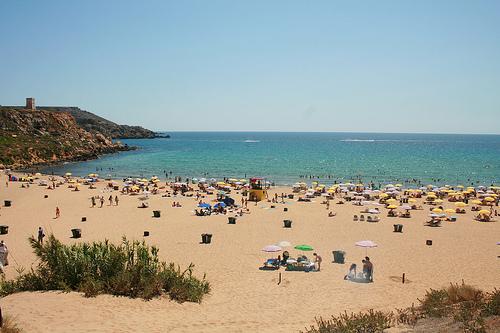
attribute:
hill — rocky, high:
[1, 107, 128, 169]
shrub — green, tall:
[2, 234, 211, 304]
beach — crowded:
[0, 173, 499, 332]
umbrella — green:
[294, 243, 313, 251]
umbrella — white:
[260, 243, 283, 252]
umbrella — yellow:
[477, 209, 491, 215]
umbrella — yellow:
[386, 203, 395, 210]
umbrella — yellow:
[444, 208, 454, 214]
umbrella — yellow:
[432, 199, 442, 203]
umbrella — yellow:
[407, 198, 417, 204]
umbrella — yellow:
[453, 201, 465, 208]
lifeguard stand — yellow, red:
[247, 177, 269, 200]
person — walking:
[115, 195, 119, 206]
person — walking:
[108, 194, 114, 205]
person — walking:
[99, 196, 106, 207]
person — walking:
[91, 196, 97, 209]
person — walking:
[54, 206, 61, 219]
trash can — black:
[70, 227, 83, 238]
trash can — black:
[152, 210, 160, 217]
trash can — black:
[200, 233, 213, 243]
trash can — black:
[283, 219, 292, 229]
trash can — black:
[392, 223, 403, 233]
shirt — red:
[56, 209, 61, 214]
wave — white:
[241, 138, 262, 144]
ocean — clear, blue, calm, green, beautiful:
[18, 131, 499, 188]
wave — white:
[335, 138, 376, 140]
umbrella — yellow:
[399, 205, 411, 211]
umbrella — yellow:
[482, 196, 495, 204]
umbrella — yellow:
[469, 200, 482, 205]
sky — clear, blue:
[2, 1, 500, 136]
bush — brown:
[398, 278, 499, 332]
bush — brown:
[302, 310, 396, 332]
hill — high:
[38, 107, 170, 144]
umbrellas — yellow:
[288, 183, 499, 228]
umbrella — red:
[249, 176, 264, 181]